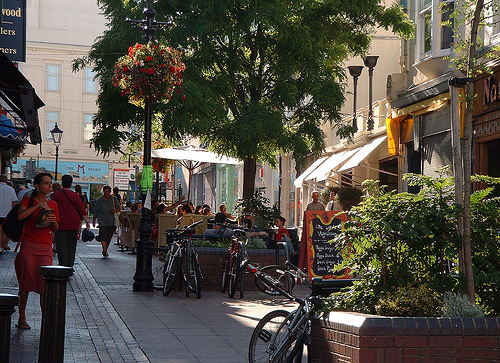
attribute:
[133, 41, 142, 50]
flower — red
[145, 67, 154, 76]
flower — red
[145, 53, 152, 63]
flower — red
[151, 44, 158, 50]
flower — red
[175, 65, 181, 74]
flower — red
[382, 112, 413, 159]
flag — yellow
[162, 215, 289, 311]
planters — red, brick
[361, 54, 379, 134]
sconces — black, decorative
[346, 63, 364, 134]
sconces — black, decorative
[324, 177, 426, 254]
leaves — green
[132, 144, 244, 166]
umbrella — white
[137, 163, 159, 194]
poster — green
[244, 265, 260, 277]
bikereflector — red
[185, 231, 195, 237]
bikereflector — red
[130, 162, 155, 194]
sign — green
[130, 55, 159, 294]
pole — small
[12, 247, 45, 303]
skirt — red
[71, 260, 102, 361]
walkway — brick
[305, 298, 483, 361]
planter — brick, red